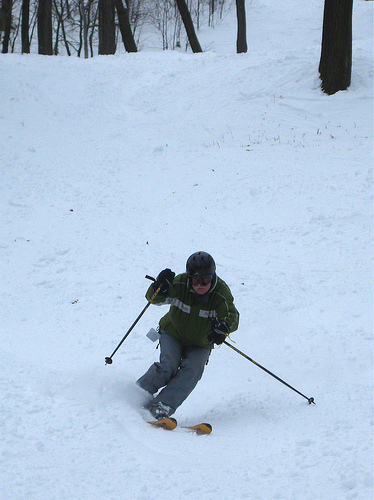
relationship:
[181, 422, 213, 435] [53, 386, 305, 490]
ski in snow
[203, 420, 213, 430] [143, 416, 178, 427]
tip of ski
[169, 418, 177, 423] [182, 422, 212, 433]
tip of ski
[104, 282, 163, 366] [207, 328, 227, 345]
pole in hand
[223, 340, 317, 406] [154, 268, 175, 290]
pole in hand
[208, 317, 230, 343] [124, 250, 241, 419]
glove on man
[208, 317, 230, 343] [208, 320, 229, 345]
glove on hand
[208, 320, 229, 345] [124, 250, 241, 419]
hand of man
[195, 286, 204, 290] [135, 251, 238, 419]
beard on man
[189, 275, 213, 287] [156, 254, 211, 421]
goggles on man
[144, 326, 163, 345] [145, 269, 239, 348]
tag on jacket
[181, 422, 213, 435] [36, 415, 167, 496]
ski on snow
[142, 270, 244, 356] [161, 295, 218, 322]
jacket with stripe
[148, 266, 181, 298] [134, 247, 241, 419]
black gloves on skier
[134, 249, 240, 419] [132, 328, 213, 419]
skier wearing pants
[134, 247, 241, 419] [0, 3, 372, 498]
skier on hill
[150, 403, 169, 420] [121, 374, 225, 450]
part of shoe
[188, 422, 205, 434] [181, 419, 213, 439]
part of board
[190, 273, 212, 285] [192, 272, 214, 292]
goggles on face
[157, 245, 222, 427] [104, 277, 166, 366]
man holding ski pole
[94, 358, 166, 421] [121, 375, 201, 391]
snow from skis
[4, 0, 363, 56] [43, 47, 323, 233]
trees above slope